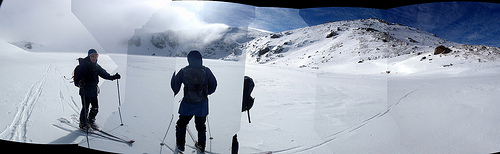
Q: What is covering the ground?
A: White snow.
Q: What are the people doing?
A: Skiing.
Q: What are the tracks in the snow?
A: Ski tracks.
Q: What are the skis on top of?
A: White snow.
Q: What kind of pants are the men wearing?
A: Snow pants.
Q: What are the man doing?
A: Skiing.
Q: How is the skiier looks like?
A: East.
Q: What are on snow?
A: Set of tracks.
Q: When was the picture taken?
A: Daytime.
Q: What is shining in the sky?
A: The Sun.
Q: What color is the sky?
A: Blue.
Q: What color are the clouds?
A: White.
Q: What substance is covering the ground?
A: Snow.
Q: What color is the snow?
A: White.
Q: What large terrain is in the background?
A: Mountains.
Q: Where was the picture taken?
A: At a ski lodge.